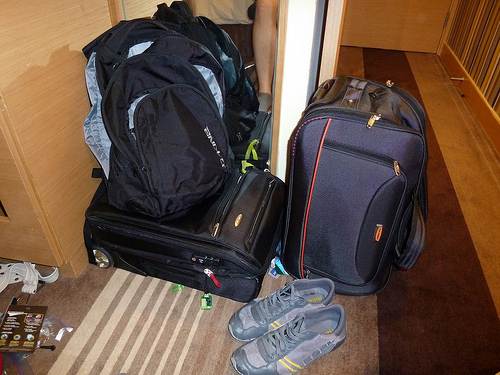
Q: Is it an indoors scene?
A: Yes, it is indoors.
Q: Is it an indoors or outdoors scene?
A: It is indoors.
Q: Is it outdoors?
A: No, it is indoors.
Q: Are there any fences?
A: No, there are no fences.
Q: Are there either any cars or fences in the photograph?
A: No, there are no fences or cars.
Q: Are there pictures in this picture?
A: No, there are no pictures.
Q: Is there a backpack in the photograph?
A: Yes, there is a backpack.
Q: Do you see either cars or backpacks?
A: Yes, there is a backpack.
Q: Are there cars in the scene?
A: No, there are no cars.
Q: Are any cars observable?
A: No, there are no cars.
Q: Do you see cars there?
A: No, there are no cars.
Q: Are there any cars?
A: No, there are no cars.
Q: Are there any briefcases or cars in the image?
A: No, there are no cars or briefcases.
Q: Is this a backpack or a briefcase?
A: This is a backpack.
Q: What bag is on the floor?
A: The bag is a backpack.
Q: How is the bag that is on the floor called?
A: The bag is a backpack.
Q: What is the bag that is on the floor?
A: The bag is a backpack.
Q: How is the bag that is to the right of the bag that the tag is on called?
A: The bag is a backpack.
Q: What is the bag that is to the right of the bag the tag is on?
A: The bag is a backpack.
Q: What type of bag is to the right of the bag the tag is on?
A: The bag is a backpack.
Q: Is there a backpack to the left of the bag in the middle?
A: No, the backpack is to the right of the bag.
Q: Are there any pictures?
A: No, there are no pictures.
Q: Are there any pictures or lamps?
A: No, there are no pictures or lamps.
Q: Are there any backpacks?
A: Yes, there is a backpack.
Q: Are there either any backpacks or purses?
A: Yes, there is a backpack.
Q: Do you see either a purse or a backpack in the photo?
A: Yes, there is a backpack.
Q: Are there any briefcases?
A: No, there are no briefcases.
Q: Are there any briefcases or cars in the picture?
A: No, there are no briefcases or cars.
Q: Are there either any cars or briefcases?
A: No, there are no briefcases or cars.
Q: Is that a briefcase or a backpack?
A: That is a backpack.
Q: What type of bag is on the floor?
A: The bag is a backpack.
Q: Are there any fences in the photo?
A: No, there are no fences.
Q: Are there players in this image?
A: No, there are no players.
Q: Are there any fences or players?
A: No, there are no players or fences.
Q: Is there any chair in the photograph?
A: No, there are no chairs.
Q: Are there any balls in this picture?
A: No, there are no balls.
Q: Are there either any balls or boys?
A: No, there are no balls or boys.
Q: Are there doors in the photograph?
A: Yes, there is a door.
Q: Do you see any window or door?
A: Yes, there is a door.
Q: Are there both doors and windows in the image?
A: No, there is a door but no windows.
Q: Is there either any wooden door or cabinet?
A: Yes, there is a wood door.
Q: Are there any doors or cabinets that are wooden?
A: Yes, the door is wooden.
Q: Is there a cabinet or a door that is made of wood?
A: Yes, the door is made of wood.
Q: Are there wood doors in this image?
A: Yes, there is a wood door.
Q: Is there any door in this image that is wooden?
A: Yes, there is a door that is wooden.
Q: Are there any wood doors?
A: Yes, there is a door that is made of wood.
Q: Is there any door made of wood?
A: Yes, there is a door that is made of wood.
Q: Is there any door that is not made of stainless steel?
A: Yes, there is a door that is made of wood.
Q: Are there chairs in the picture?
A: No, there are no chairs.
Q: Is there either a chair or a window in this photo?
A: No, there are no chairs or windows.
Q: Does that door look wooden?
A: Yes, the door is wooden.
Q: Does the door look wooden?
A: Yes, the door is wooden.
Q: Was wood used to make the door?
A: Yes, the door is made of wood.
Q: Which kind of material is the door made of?
A: The door is made of wood.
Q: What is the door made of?
A: The door is made of wood.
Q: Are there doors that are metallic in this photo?
A: No, there is a door but it is wooden.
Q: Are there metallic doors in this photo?
A: No, there is a door but it is wooden.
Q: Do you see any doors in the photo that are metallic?
A: No, there is a door but it is wooden.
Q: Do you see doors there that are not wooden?
A: No, there is a door but it is wooden.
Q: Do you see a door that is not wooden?
A: No, there is a door but it is wooden.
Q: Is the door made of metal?
A: No, the door is made of wood.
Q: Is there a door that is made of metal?
A: No, there is a door but it is made of wood.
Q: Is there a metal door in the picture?
A: No, there is a door but it is made of wood.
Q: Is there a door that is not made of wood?
A: No, there is a door but it is made of wood.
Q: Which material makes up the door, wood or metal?
A: The door is made of wood.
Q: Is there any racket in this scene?
A: No, there are no rackets.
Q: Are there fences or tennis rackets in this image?
A: No, there are no tennis rackets or fences.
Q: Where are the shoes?
A: The shoes are on the ground.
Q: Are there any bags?
A: Yes, there is a bag.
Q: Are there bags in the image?
A: Yes, there is a bag.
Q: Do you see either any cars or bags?
A: Yes, there is a bag.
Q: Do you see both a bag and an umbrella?
A: No, there is a bag but no umbrellas.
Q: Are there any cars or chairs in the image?
A: No, there are no cars or chairs.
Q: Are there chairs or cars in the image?
A: No, there are no cars or chairs.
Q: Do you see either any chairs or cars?
A: No, there are no cars or chairs.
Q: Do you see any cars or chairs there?
A: No, there are no cars or chairs.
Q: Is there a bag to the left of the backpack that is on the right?
A: Yes, there is a bag to the left of the backpack.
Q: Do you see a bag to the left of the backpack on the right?
A: Yes, there is a bag to the left of the backpack.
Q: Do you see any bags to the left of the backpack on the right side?
A: Yes, there is a bag to the left of the backpack.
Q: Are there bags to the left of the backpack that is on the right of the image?
A: Yes, there is a bag to the left of the backpack.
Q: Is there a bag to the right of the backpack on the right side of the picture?
A: No, the bag is to the left of the backpack.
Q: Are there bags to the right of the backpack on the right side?
A: No, the bag is to the left of the backpack.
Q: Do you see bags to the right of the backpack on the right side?
A: No, the bag is to the left of the backpack.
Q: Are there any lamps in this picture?
A: No, there are no lamps.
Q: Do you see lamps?
A: No, there are no lamps.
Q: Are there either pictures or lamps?
A: No, there are no lamps or pictures.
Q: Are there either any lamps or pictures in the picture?
A: No, there are no lamps or pictures.